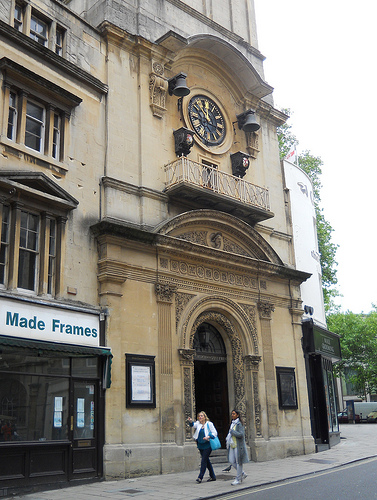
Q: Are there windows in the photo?
A: Yes, there are windows.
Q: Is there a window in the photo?
A: Yes, there are windows.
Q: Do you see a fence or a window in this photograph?
A: Yes, there are windows.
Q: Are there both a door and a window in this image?
A: Yes, there are both a window and a door.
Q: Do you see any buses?
A: No, there are no buses.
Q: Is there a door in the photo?
A: Yes, there is a door.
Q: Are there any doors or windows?
A: Yes, there is a door.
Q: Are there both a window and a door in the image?
A: Yes, there are both a door and a window.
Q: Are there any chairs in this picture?
A: No, there are no chairs.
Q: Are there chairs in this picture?
A: No, there are no chairs.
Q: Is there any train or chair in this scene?
A: No, there are no chairs or trains.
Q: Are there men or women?
A: Yes, there is a woman.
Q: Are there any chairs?
A: No, there are no chairs.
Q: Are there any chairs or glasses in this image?
A: No, there are no chairs or glasses.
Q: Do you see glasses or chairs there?
A: No, there are no chairs or glasses.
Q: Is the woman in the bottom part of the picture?
A: Yes, the woman is in the bottom of the image.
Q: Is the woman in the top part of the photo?
A: No, the woman is in the bottom of the image.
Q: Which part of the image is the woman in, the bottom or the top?
A: The woman is in the bottom of the image.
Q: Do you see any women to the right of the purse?
A: Yes, there is a woman to the right of the purse.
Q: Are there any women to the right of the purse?
A: Yes, there is a woman to the right of the purse.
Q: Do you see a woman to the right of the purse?
A: Yes, there is a woman to the right of the purse.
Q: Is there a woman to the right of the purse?
A: Yes, there is a woman to the right of the purse.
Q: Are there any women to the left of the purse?
A: No, the woman is to the right of the purse.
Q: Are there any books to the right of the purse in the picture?
A: No, there is a woman to the right of the purse.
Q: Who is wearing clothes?
A: The woman is wearing clothes.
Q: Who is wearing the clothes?
A: The woman is wearing clothes.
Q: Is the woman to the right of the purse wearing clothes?
A: Yes, the woman is wearing clothes.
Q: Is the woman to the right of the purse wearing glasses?
A: No, the woman is wearing clothes.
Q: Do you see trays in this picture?
A: No, there are no trays.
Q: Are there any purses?
A: Yes, there is a purse.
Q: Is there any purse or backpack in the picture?
A: Yes, there is a purse.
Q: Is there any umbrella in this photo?
A: No, there are no umbrellas.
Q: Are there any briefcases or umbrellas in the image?
A: No, there are no umbrellas or briefcases.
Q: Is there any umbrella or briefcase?
A: No, there are no umbrellas or briefcases.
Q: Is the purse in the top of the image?
A: No, the purse is in the bottom of the image.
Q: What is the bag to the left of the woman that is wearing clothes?
A: The bag is a purse.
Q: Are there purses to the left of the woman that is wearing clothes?
A: Yes, there is a purse to the left of the woman.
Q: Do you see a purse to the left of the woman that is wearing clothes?
A: Yes, there is a purse to the left of the woman.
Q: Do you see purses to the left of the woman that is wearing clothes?
A: Yes, there is a purse to the left of the woman.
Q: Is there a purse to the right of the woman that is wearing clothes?
A: No, the purse is to the left of the woman.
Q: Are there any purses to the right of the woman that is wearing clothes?
A: No, the purse is to the left of the woman.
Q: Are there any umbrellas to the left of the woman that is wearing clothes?
A: No, there is a purse to the left of the woman.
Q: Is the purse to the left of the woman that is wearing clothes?
A: Yes, the purse is to the left of the woman.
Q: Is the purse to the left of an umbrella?
A: No, the purse is to the left of the woman.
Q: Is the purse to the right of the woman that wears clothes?
A: No, the purse is to the left of the woman.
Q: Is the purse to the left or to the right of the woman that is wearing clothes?
A: The purse is to the left of the woman.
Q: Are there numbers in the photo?
A: Yes, there are numbers.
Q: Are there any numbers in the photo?
A: Yes, there are numbers.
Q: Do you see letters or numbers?
A: Yes, there are numbers.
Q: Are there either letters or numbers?
A: Yes, there are numbers.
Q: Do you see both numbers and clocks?
A: Yes, there are both numbers and a clock.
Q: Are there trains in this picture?
A: No, there are no trains.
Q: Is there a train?
A: No, there are no trains.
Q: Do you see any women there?
A: Yes, there is a woman.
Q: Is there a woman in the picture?
A: Yes, there is a woman.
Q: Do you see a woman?
A: Yes, there is a woman.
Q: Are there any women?
A: Yes, there is a woman.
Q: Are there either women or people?
A: Yes, there is a woman.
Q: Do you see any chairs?
A: No, there are no chairs.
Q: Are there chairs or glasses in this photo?
A: No, there are no chairs or glasses.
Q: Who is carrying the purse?
A: The woman is carrying the purse.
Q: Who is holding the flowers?
A: The woman is holding the flowers.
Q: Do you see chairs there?
A: No, there are no chairs.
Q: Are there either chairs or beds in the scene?
A: No, there are no chairs or beds.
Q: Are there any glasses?
A: No, there are no glasses.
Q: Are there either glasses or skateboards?
A: No, there are no glasses or skateboards.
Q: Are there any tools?
A: No, there are no tools.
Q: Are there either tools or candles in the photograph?
A: No, there are no tools or candles.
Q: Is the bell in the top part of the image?
A: Yes, the bell is in the top of the image.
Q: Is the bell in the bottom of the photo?
A: No, the bell is in the top of the image.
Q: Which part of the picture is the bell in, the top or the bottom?
A: The bell is in the top of the image.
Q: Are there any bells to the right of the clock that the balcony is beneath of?
A: Yes, there is a bell to the right of the clock.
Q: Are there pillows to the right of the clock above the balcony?
A: No, there is a bell to the right of the clock.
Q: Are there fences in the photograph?
A: No, there are no fences.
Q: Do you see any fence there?
A: No, there are no fences.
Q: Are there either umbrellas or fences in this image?
A: No, there are no fences or umbrellas.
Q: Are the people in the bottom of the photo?
A: Yes, the people are in the bottom of the image.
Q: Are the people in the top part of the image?
A: No, the people are in the bottom of the image.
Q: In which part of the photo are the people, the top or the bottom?
A: The people are in the bottom of the image.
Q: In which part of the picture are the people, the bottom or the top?
A: The people are in the bottom of the image.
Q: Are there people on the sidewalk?
A: Yes, there are people on the sidewalk.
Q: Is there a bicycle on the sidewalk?
A: No, there are people on the sidewalk.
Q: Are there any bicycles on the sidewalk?
A: No, there are people on the sidewalk.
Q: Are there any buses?
A: No, there are no buses.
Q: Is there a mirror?
A: No, there are no mirrors.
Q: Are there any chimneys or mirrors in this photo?
A: No, there are no mirrors or chimneys.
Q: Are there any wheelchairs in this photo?
A: No, there are no wheelchairs.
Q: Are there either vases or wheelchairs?
A: No, there are no wheelchairs or vases.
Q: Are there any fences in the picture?
A: No, there are no fences.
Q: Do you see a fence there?
A: No, there are no fences.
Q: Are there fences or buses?
A: No, there are no fences or buses.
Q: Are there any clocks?
A: Yes, there is a clock.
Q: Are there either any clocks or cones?
A: Yes, there is a clock.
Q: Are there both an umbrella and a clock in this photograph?
A: No, there is a clock but no umbrellas.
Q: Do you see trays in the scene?
A: No, there are no trays.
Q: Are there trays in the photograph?
A: No, there are no trays.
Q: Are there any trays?
A: No, there are no trays.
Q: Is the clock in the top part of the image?
A: Yes, the clock is in the top of the image.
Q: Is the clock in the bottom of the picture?
A: No, the clock is in the top of the image.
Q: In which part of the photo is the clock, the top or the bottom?
A: The clock is in the top of the image.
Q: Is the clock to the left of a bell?
A: Yes, the clock is to the left of a bell.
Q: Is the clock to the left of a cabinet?
A: No, the clock is to the left of a bell.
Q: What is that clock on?
A: The clock is on the building.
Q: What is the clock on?
A: The clock is on the building.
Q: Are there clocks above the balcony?
A: Yes, there is a clock above the balcony.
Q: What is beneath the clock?
A: The balcony is beneath the clock.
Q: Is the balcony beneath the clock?
A: Yes, the balcony is beneath the clock.